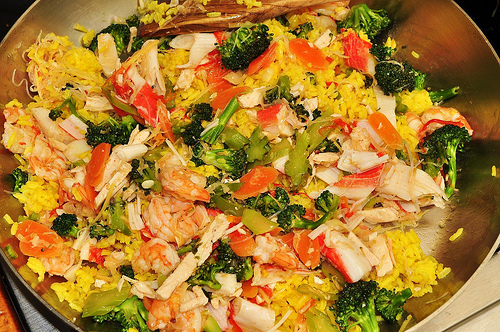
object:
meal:
[5, 0, 473, 332]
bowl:
[2, 0, 500, 331]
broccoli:
[213, 22, 274, 72]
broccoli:
[423, 124, 472, 198]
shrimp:
[182, 213, 199, 233]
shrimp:
[160, 166, 211, 204]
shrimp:
[138, 238, 180, 274]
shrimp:
[145, 288, 202, 331]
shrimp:
[420, 106, 474, 137]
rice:
[340, 96, 356, 106]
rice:
[409, 261, 433, 282]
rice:
[74, 23, 96, 47]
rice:
[12, 179, 60, 213]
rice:
[58, 286, 88, 295]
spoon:
[138, 0, 346, 36]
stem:
[357, 320, 381, 331]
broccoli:
[328, 280, 379, 331]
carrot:
[365, 111, 402, 149]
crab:
[341, 32, 373, 73]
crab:
[318, 232, 373, 284]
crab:
[322, 162, 385, 198]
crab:
[132, 81, 157, 127]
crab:
[374, 163, 444, 201]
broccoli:
[85, 114, 138, 146]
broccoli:
[49, 212, 79, 237]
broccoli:
[90, 295, 148, 331]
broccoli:
[375, 61, 426, 97]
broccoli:
[336, 2, 390, 38]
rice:
[27, 257, 46, 283]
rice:
[449, 228, 464, 242]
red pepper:
[139, 225, 156, 243]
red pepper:
[210, 86, 251, 112]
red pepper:
[247, 42, 277, 76]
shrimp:
[28, 147, 68, 181]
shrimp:
[404, 113, 426, 144]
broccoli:
[90, 22, 129, 59]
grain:
[54, 35, 70, 46]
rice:
[50, 53, 83, 75]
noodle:
[407, 159, 425, 215]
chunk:
[155, 252, 199, 301]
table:
[0, 270, 17, 331]